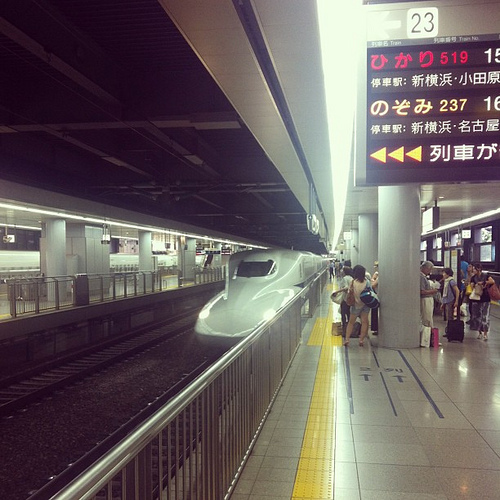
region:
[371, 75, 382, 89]
white foreign letter on sign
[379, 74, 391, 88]
black key on keyboard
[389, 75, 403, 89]
black key on keyboard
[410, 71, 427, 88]
black key on keyboard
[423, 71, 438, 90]
black key on keyboard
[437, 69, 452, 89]
black key on keyboard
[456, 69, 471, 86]
black key on keyboard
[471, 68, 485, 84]
black key on keyboard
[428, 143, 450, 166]
black key on keyboard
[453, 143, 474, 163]
black key on keyboard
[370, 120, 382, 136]
white foreign letter on sign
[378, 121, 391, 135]
red design on cushion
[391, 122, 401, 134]
red design on cushion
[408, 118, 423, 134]
red design on cushion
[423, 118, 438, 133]
red design on cushion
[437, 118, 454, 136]
red design on cushion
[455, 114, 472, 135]
red design on cushion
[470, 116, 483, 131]
red design on cushion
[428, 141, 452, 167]
red design on cushion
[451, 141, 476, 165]
red design on cushion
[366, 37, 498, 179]
asian lettering on sign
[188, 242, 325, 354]
bullet train parked at station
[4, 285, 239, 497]
railway tracks on ground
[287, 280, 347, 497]
yellow line on floor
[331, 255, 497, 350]
people waiting for the train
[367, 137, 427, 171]
three yellow arrows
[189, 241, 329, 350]
white train is sleek and smooth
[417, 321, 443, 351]
white and pink shopping bags on floor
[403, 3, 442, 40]
platform number in white and black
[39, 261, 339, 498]
metal railing protecting people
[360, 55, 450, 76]
a sign written in hiragana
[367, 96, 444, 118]
writing that reads nozomi in japanese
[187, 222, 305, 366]
a train approaching the platform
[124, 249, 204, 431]
a bunch of black railroad tracks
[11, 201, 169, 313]
the opposite side of the platform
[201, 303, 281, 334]
the headlights on a speed train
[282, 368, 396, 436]
the safety line of a highspeed train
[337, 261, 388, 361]
a person waiting for the train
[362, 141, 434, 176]
arrows pointing to the left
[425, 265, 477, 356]
a bunch of people with suitcases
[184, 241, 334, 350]
The train is white.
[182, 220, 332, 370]
The train is moving.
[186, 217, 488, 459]
The train is pulling into the train station.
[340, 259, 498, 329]
The people are waiting.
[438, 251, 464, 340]
She has luggage.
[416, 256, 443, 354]
She has two bags.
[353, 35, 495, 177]
The lights are on.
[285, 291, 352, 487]
The paint is yellow.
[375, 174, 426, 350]
The pillar is white.